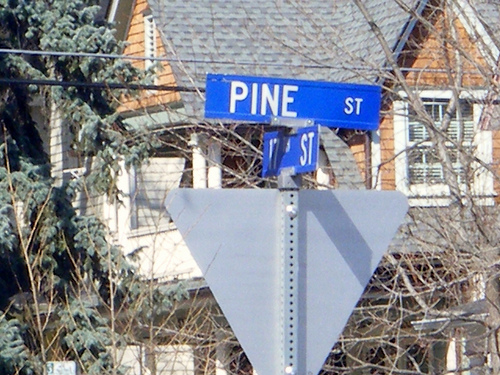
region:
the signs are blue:
[192, 46, 388, 195]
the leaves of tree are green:
[1, 1, 174, 367]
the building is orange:
[108, 3, 493, 250]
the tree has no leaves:
[289, 0, 493, 370]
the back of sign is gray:
[160, 175, 414, 360]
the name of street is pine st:
[211, 70, 411, 131]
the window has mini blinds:
[401, 82, 492, 178]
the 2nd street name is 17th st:
[257, 130, 336, 183]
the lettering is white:
[228, 76, 370, 138]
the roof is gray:
[155, 1, 486, 134]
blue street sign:
[202, 75, 382, 121]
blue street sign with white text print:
[205, 80, 380, 125]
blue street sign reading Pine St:
[205, 80, 375, 116]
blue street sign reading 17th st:
[260, 135, 315, 170]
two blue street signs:
[205, 75, 380, 170]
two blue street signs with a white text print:
[200, 76, 381, 171]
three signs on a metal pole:
[160, 73, 398, 373]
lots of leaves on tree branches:
[1, 3, 127, 98]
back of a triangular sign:
[166, 186, 408, 374]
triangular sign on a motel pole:
[164, 188, 409, 373]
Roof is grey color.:
[201, 18, 378, 58]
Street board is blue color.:
[198, 71, 390, 174]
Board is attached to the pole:
[265, 148, 347, 324]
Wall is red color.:
[111, 53, 185, 99]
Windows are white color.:
[95, 108, 497, 243]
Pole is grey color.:
[273, 197, 299, 372]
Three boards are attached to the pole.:
[195, 72, 388, 363]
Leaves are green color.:
[15, 11, 100, 71]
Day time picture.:
[18, 18, 488, 358]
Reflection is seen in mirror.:
[133, 133, 200, 208]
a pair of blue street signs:
[203, 72, 378, 175]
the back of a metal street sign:
[162, 187, 409, 374]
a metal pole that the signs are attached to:
[276, 170, 299, 374]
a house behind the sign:
[86, 0, 498, 373]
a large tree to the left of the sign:
[1, 2, 166, 373]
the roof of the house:
[107, 0, 497, 125]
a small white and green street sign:
[43, 360, 74, 374]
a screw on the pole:
[287, 207, 297, 217]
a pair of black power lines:
[0, 44, 497, 105]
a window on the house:
[400, 92, 478, 184]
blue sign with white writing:
[190, 46, 388, 142]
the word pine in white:
[226, 81, 303, 120]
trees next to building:
[9, 175, 107, 282]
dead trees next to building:
[414, 196, 478, 292]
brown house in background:
[413, 21, 465, 82]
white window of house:
[391, 101, 479, 201]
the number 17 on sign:
[249, 133, 289, 178]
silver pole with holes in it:
[265, 201, 323, 314]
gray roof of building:
[187, 12, 284, 69]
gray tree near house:
[401, 205, 475, 325]